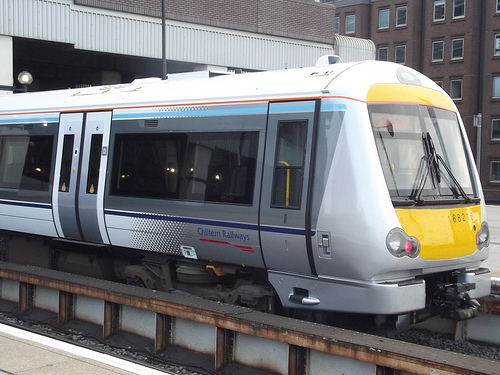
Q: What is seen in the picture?
A: Train.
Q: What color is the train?
A: Yellow and grey.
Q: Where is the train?
A: In the track.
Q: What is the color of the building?
A: Brown.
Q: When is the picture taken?
A: Daytime.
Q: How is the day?
A: Sunny.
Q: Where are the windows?
A: In the wall of the building.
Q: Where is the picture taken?
A: At a train station.